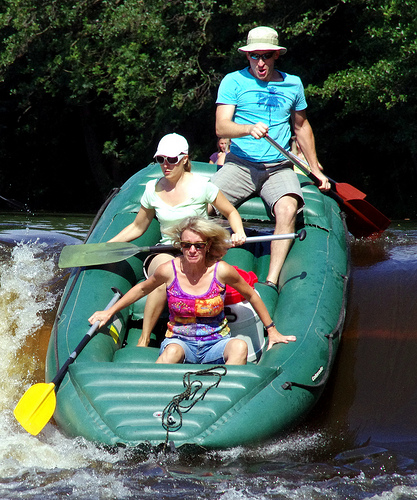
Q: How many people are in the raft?
A: Three.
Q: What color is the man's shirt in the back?
A: Blue.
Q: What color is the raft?
A: Green.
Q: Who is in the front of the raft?
A: A woman.